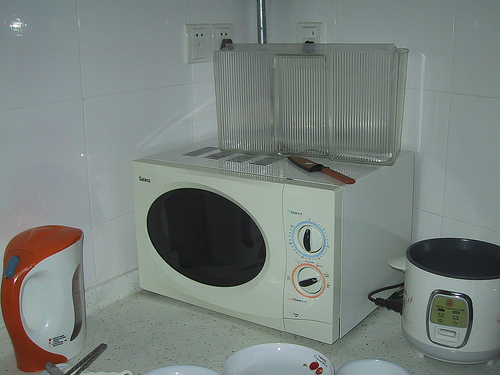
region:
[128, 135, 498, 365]
White kitchen appliances on the counter.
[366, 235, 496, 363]
White slow cooker on the counter.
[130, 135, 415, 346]
White microwave on counter.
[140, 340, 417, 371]
White dinnerware on counter top.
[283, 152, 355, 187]
Kitchen utensil on top of microwave.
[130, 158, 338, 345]
Black tinted window on microwave's door.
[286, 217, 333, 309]
Two control knobs beside the microwave's door.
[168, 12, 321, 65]
Electrical outlet on the wall.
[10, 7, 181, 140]
White ceramic wall tiles.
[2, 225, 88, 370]
Red and white beverage pitcher.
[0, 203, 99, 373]
an orange and white pitcher with a blue button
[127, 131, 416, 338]
a white microwave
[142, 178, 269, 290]
a dark oval microwave window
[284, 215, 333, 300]
two dials with blue and orange rings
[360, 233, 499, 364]
white crockpot with a black inside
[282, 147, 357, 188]
small knife with a brown handle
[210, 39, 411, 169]
a large plastic case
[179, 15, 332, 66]
three white outlets with black plugs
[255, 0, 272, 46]
a silver pipe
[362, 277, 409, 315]
a black electrical plug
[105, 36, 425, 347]
microwave in kitchen corner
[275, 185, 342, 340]
dials on panel of microwave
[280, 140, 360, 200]
short knife on corner of microwave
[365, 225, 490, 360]
electric cooker with plug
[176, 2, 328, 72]
white electrical outlets on walls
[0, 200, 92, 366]
red and white dispenser against wall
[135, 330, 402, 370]
edge of plates on counter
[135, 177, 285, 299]
oval window on microwave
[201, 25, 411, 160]
rectangular and ridged plastic on microwave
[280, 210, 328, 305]
blue and orange rings around dials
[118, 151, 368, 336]
off-white microwave with dials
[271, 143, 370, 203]
wood-handled knife on top of the microwave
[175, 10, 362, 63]
two-pronged electrical outlets on the wall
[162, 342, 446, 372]
assorted white bowls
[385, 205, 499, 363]
rice cooker with Japanese writing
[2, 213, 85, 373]
tall red and white water filter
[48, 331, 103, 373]
pair of black chopsticks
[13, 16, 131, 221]
glossy white kitchen tiles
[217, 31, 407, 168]
clear trays perched on the microwave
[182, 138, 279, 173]
four vents on the top of the microwave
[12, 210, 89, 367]
Orange and white electronic devide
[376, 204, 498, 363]
White, black and green crock pot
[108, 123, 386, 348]
Black and white microwave oven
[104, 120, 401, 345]
Black and white microwave oven on white table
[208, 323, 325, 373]
White bowl on white table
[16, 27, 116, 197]
White wall in kitchen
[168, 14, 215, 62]
White wall socket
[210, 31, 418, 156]
Opaque container on white microwave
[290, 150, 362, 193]
Red knife on white microwave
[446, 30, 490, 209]
White wall in kitchen